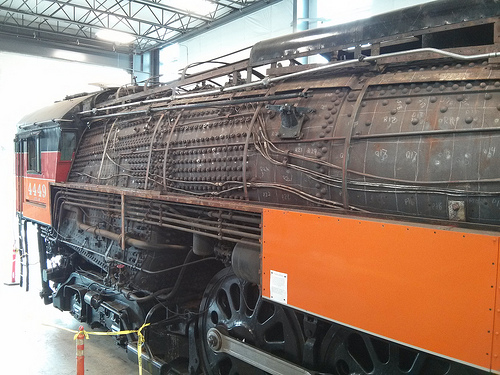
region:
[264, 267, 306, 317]
white square on orange side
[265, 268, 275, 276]
small black screw in white sign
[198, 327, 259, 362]
large screw on train wheel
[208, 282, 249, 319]
grooves in shiny train wheel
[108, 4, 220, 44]
large overhead beams in train depot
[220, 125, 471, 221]
steel line running across train sides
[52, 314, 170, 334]
long tied yellow ribbon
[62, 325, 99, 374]
white and orange pole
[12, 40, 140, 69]
small portion of silver door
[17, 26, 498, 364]
large old fashioned train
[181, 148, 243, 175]
steal rivets on a locomotive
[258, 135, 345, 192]
fastened cables on a train engine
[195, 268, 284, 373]
the wheel of a train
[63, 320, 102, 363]
and orange post with yellow tied tape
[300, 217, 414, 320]
an orange painted panel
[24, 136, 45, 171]
a window on a train locomotive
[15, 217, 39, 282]
metal ladder on a train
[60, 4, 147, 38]
black metal support girders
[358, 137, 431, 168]
chalk writing on a train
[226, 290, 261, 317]
spokes of a train wheel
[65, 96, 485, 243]
Old train on display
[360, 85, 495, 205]
Misc. writing on old train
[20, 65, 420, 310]
old train inside building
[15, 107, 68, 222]
orange,black, and red train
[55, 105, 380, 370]
Vintage train on display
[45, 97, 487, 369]
ancient train on display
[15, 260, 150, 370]
Roped off train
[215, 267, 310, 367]
Large train wheels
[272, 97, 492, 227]
handwritten measurements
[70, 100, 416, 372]
old iron train on display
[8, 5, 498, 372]
Old locomotive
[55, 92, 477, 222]
Locomotive is rusted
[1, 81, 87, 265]
Front of locomotive is black, red and orance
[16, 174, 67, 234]
Locomotive number is 4449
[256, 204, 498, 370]
Side panel of locomotive is orange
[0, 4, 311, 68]
Locomotive is under a roof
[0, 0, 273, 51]
Roof structure is metal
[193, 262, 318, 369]
Wheels of locomotive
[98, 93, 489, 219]
Wires of locomotive are visible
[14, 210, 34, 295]
Stair to get into the locomotive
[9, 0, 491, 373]
Large rusty train engine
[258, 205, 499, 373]
orange panel on side of train engine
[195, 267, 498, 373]
large black train wheels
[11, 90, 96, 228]
front of engine painted red and orange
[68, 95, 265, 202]
train has many rivets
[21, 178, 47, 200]
train number 4449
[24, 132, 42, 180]
window in train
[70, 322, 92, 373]
orange and white cone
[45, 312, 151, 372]
yellow caution tape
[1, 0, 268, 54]
scaffolding above train